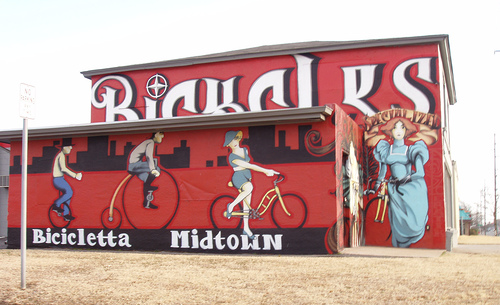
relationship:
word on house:
[91, 49, 445, 125] [3, 34, 468, 259]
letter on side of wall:
[338, 58, 385, 119] [88, 40, 447, 246]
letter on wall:
[338, 58, 385, 119] [88, 40, 447, 246]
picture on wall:
[353, 104, 441, 247] [88, 40, 447, 246]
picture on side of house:
[353, 104, 441, 247] [3, 34, 468, 259]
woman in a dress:
[361, 107, 442, 248] [370, 140, 434, 247]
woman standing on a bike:
[223, 127, 258, 234] [210, 175, 312, 229]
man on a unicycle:
[53, 138, 81, 221] [47, 182, 74, 228]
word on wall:
[91, 49, 445, 125] [88, 40, 447, 246]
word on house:
[170, 229, 283, 251] [3, 34, 468, 259]